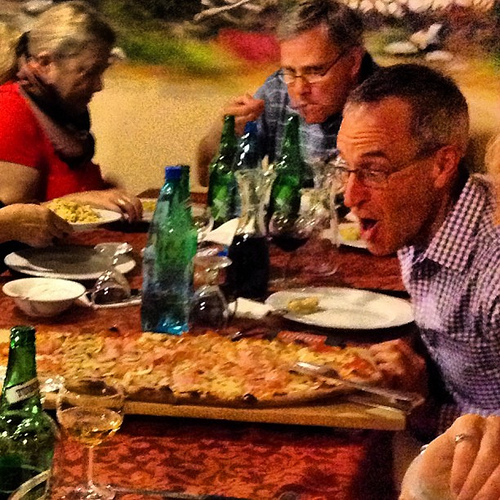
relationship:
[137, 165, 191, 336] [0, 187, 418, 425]
bottle on a table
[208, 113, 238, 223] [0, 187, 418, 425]
bottle on a table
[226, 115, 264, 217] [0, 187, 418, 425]
bottle on a table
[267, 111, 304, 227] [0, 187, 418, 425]
bottle on a table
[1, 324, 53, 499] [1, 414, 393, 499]
bottle on a table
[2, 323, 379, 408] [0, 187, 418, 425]
pizza on a table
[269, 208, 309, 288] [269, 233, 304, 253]
glass has wine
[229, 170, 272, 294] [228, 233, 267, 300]
carafe has wine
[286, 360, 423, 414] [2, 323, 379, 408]
tong on pizza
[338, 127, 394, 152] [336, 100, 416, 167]
wrinkles on a forehead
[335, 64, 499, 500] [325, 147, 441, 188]
man wearing glasses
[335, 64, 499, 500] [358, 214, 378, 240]
man has mouth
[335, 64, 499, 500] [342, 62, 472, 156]
man has hair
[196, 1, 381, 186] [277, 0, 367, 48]
man has hair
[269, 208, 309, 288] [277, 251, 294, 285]
glass has a stem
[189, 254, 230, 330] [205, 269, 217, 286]
glass has a stem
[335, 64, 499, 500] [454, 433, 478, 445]
man wearing a ring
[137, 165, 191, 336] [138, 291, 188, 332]
bottle has water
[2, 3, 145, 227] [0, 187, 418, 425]
lady sitting at table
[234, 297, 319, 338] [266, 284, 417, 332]
spoon on a plate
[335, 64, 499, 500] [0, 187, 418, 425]
man at a table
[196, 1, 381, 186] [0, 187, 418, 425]
man at a table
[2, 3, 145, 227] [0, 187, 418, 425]
lady at a table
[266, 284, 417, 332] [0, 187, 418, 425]
plate on a table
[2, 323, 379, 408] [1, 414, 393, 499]
pizza on a table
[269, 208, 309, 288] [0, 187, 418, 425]
glass on a table